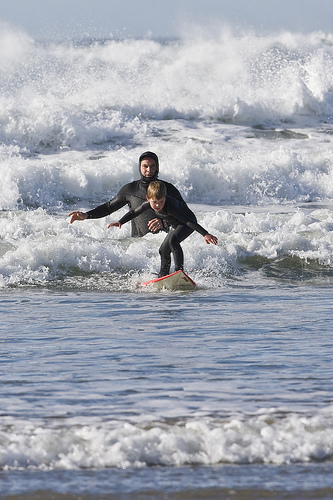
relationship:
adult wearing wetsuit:
[67, 149, 197, 238] [86, 152, 181, 235]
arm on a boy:
[166, 211, 208, 233] [107, 179, 218, 277]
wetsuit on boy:
[116, 199, 207, 276] [107, 179, 218, 277]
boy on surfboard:
[102, 177, 223, 274] [141, 268, 197, 289]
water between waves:
[0, 21, 333, 500] [31, 179, 329, 274]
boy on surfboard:
[105, 177, 219, 279] [143, 271, 200, 286]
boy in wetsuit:
[102, 177, 223, 274] [120, 203, 207, 270]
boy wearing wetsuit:
[105, 177, 219, 279] [151, 185, 202, 250]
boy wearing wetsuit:
[105, 177, 219, 279] [116, 199, 207, 276]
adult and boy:
[67, 149, 161, 238] [105, 177, 219, 279]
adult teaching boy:
[67, 149, 197, 238] [102, 177, 223, 274]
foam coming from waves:
[28, 57, 214, 146] [4, 26, 330, 307]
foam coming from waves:
[0, 411, 333, 475] [4, 26, 330, 307]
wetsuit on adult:
[71, 166, 184, 230] [67, 149, 197, 238]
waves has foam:
[4, 13, 317, 297] [4, 411, 327, 465]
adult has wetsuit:
[67, 149, 197, 238] [84, 180, 180, 242]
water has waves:
[1, 248, 331, 415] [0, 17, 332, 281]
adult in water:
[67, 149, 197, 238] [2, 34, 332, 486]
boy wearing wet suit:
[105, 177, 219, 279] [143, 199, 195, 254]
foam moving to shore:
[0, 411, 333, 475] [1, 471, 330, 499]